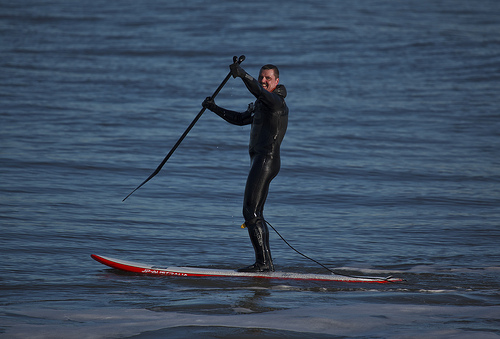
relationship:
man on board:
[206, 44, 305, 271] [88, 247, 408, 288]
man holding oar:
[206, 44, 305, 271] [115, 49, 250, 205]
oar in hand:
[115, 49, 250, 205] [222, 47, 247, 81]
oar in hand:
[115, 49, 250, 205] [200, 92, 217, 114]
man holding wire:
[206, 44, 305, 271] [260, 213, 399, 281]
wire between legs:
[260, 213, 399, 281] [241, 165, 286, 274]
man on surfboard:
[206, 44, 305, 271] [88, 247, 408, 288]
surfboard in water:
[88, 247, 408, 288] [3, 5, 500, 333]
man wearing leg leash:
[206, 44, 305, 271] [260, 213, 399, 281]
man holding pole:
[206, 44, 305, 271] [115, 49, 250, 205]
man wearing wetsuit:
[206, 44, 305, 271] [219, 81, 290, 271]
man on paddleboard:
[206, 44, 305, 271] [88, 247, 408, 288]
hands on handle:
[203, 57, 246, 113] [115, 49, 250, 205]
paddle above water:
[115, 49, 250, 205] [3, 5, 500, 333]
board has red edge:
[88, 247, 408, 288] [97, 264, 403, 284]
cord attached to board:
[260, 213, 399, 281] [88, 247, 408, 288]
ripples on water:
[27, 28, 205, 79] [3, 5, 500, 333]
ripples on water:
[345, 33, 461, 87] [3, 5, 500, 333]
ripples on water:
[340, 120, 473, 216] [3, 5, 500, 333]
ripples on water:
[32, 167, 117, 229] [3, 5, 500, 333]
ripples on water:
[225, 7, 367, 65] [3, 5, 500, 333]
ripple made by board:
[320, 262, 496, 300] [88, 247, 408, 288]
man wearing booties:
[206, 44, 305, 271] [242, 235, 280, 275]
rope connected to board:
[260, 213, 399, 281] [88, 247, 408, 288]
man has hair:
[206, 44, 305, 271] [262, 63, 282, 76]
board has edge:
[88, 247, 408, 288] [97, 264, 403, 284]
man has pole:
[206, 44, 305, 271] [115, 49, 250, 205]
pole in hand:
[115, 49, 250, 205] [222, 47, 247, 81]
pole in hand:
[115, 49, 250, 205] [200, 92, 217, 114]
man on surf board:
[206, 44, 305, 271] [88, 247, 408, 288]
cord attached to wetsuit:
[260, 213, 399, 281] [219, 81, 290, 271]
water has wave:
[3, 5, 500, 333] [320, 262, 496, 300]